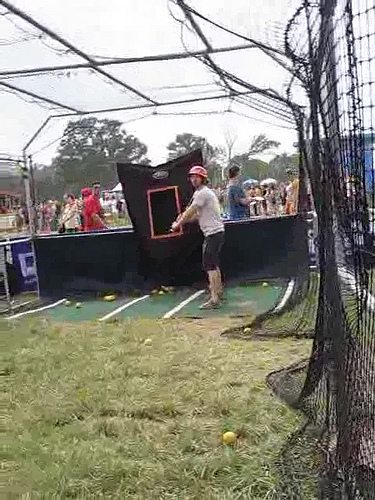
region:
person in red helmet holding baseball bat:
[147, 159, 244, 320]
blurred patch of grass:
[45, 362, 106, 453]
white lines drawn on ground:
[5, 282, 280, 330]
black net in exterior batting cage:
[228, 19, 373, 494]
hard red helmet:
[182, 159, 213, 182]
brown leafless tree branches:
[219, 127, 242, 160]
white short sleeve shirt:
[182, 188, 230, 234]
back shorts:
[191, 226, 227, 273]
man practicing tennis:
[159, 158, 238, 315]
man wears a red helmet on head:
[173, 158, 224, 214]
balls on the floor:
[49, 270, 284, 342]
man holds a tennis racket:
[166, 160, 242, 320]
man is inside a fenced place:
[5, 9, 373, 498]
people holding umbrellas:
[242, 167, 283, 210]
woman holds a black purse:
[54, 189, 80, 236]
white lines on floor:
[6, 282, 303, 324]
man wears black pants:
[168, 162, 233, 308]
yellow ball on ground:
[212, 429, 234, 440]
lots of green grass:
[47, 417, 148, 467]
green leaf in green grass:
[69, 380, 95, 407]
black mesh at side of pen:
[287, 335, 364, 377]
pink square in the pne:
[139, 182, 187, 238]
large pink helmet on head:
[182, 164, 221, 182]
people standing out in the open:
[41, 175, 106, 215]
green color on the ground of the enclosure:
[138, 298, 155, 323]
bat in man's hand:
[164, 187, 199, 236]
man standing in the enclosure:
[153, 158, 250, 269]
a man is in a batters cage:
[147, 142, 261, 338]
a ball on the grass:
[188, 402, 250, 471]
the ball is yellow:
[183, 403, 252, 465]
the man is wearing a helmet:
[171, 154, 219, 192]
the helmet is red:
[181, 149, 215, 196]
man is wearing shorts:
[182, 223, 239, 295]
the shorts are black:
[184, 225, 240, 286]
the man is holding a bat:
[136, 179, 246, 265]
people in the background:
[39, 162, 135, 235]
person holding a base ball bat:
[164, 157, 232, 310]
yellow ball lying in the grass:
[220, 429, 243, 446]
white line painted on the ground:
[158, 285, 208, 324]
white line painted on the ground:
[274, 274, 296, 310]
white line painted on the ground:
[96, 289, 151, 323]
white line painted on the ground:
[0, 295, 68, 323]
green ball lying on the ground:
[73, 300, 82, 309]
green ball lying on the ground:
[103, 291, 114, 304]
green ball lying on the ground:
[63, 297, 70, 307]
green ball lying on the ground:
[259, 278, 268, 289]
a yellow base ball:
[220, 430, 238, 445]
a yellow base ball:
[142, 337, 152, 345]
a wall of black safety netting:
[232, 37, 373, 495]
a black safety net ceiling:
[1, 0, 332, 153]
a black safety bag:
[116, 146, 204, 290]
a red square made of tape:
[143, 182, 186, 241]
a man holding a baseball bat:
[166, 163, 227, 309]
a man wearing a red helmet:
[169, 163, 226, 310]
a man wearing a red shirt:
[81, 182, 107, 229]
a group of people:
[25, 135, 310, 300]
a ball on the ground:
[218, 416, 244, 449]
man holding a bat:
[171, 160, 243, 307]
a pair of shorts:
[195, 231, 227, 278]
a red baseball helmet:
[188, 162, 209, 181]